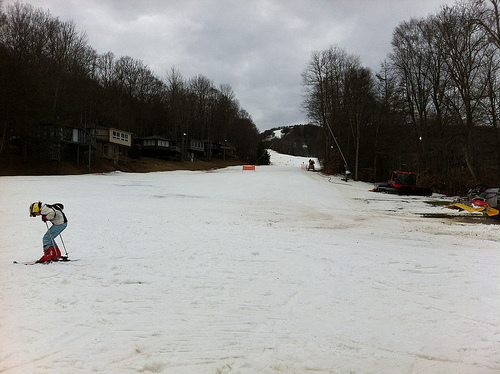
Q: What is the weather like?
A: Cloudy.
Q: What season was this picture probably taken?
A: Winter.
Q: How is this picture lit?
A: Natural light.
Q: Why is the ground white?
A: Covered in snow.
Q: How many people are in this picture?
A: One.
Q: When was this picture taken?
A: Daytime.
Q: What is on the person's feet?
A: Skis.